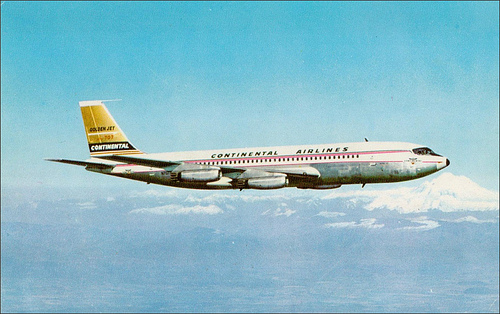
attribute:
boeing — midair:
[45, 100, 452, 192]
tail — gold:
[78, 100, 148, 157]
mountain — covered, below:
[352, 171, 499, 228]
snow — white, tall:
[405, 173, 497, 202]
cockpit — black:
[413, 146, 450, 168]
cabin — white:
[182, 150, 373, 162]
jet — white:
[44, 100, 451, 194]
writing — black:
[211, 145, 355, 163]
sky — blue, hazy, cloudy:
[0, 0, 499, 189]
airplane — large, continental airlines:
[46, 99, 452, 190]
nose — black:
[445, 157, 452, 167]